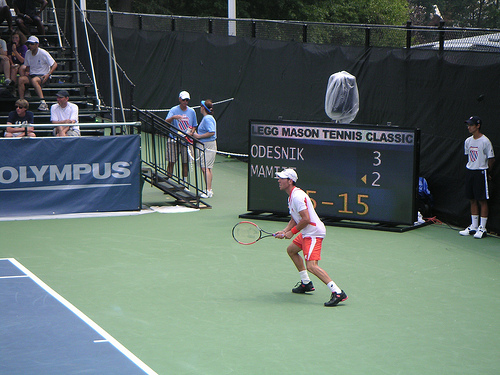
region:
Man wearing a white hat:
[275, 168, 298, 181]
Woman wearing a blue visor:
[200, 100, 213, 110]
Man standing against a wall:
[456, 115, 494, 241]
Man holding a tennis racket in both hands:
[231, 220, 284, 247]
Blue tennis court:
[0, 255, 160, 372]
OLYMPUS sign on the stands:
[0, 136, 144, 210]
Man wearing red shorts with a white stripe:
[291, 230, 322, 260]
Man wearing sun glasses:
[16, 105, 26, 110]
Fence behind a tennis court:
[77, 10, 499, 227]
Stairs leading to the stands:
[133, 110, 213, 206]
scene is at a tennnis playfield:
[43, 140, 489, 352]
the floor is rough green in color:
[246, 298, 458, 362]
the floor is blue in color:
[25, 329, 105, 361]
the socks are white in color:
[312, 277, 348, 289]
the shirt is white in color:
[456, 135, 493, 161]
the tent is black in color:
[173, 45, 292, 107]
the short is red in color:
[288, 236, 328, 266]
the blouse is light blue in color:
[201, 119, 221, 139]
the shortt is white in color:
[206, 143, 220, 171]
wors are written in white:
[12, 145, 130, 193]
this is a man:
[275, 168, 344, 305]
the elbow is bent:
[301, 210, 310, 222]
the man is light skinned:
[308, 257, 325, 271]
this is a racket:
[229, 213, 264, 245]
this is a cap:
[277, 169, 301, 180]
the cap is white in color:
[286, 167, 308, 177]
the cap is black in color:
[463, 109, 482, 124]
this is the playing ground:
[73, 221, 198, 369]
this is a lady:
[193, 97, 220, 222]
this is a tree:
[333, 10, 395, 23]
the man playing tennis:
[231, 167, 346, 307]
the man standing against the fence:
[458, 115, 494, 239]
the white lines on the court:
[0, 256, 158, 373]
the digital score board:
[247, 120, 418, 227]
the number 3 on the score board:
[372, 148, 381, 166]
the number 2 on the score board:
[370, 170, 380, 187]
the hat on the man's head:
[275, 169, 297, 184]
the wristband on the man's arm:
[288, 225, 298, 234]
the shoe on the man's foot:
[324, 290, 347, 305]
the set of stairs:
[130, 105, 210, 210]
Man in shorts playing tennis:
[231, 165, 350, 307]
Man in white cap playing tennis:
[230, 167, 351, 307]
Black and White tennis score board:
[245, 116, 421, 228]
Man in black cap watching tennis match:
[48, 88, 79, 138]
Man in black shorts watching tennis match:
[460, 113, 499, 244]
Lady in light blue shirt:
[191, 97, 218, 200]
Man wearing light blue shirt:
[162, 90, 197, 190]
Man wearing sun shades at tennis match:
[5, 97, 37, 139]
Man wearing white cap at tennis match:
[164, 88, 199, 193]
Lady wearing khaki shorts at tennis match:
[193, 97, 219, 199]